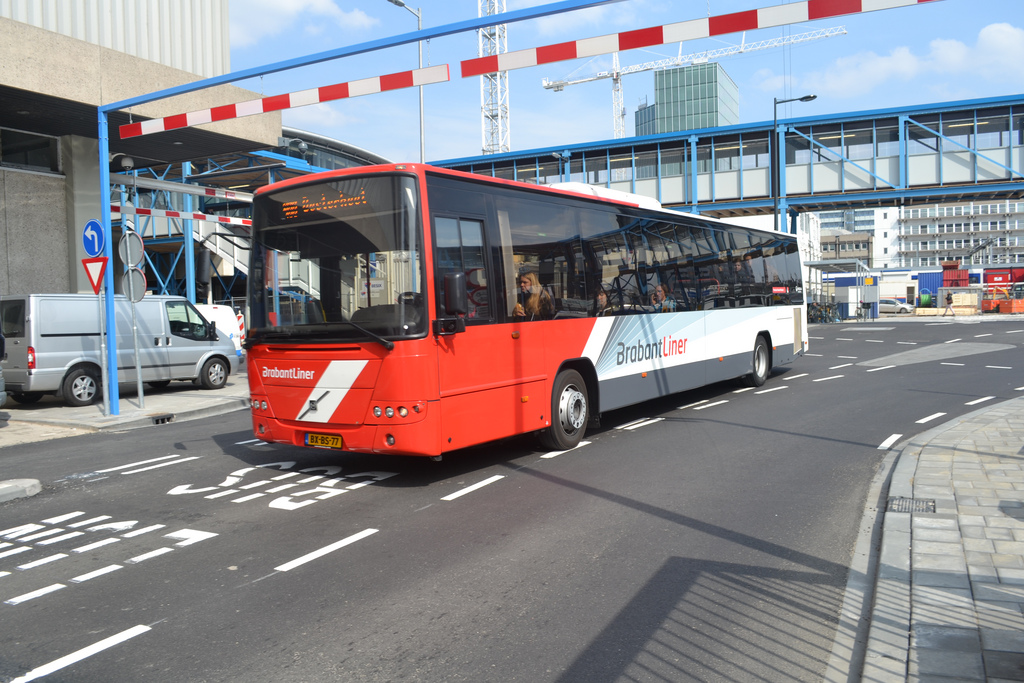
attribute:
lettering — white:
[263, 362, 317, 386]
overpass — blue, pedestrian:
[450, 93, 1020, 193]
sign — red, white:
[78, 258, 111, 293]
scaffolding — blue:
[117, 141, 315, 320]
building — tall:
[649, 62, 742, 139]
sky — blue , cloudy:
[231, 11, 1020, 114]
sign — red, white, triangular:
[80, 255, 115, 294]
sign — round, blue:
[81, 217, 108, 256]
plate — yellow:
[302, 432, 341, 449]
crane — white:
[548, 24, 846, 101]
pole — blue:
[98, 108, 121, 416]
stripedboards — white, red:
[121, 1, 944, 142]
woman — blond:
[516, 264, 561, 312]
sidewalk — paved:
[866, 400, 1021, 679]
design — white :
[283, 353, 368, 434]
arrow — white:
[81, 217, 99, 263]